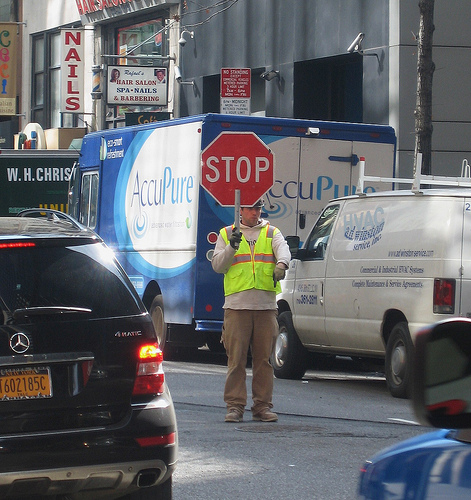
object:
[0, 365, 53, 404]
license plate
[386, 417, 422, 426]
line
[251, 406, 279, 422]
shoes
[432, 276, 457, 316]
tail light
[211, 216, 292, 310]
sweatshirt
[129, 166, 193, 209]
logo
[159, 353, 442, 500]
asphalt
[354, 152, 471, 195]
rack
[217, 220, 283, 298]
vest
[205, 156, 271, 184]
white lettering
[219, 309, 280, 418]
pants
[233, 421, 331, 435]
manhole cover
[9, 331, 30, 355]
metal logo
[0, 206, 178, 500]
suv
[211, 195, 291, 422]
man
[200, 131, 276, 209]
sign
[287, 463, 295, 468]
patch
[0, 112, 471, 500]
traffic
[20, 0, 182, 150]
salon